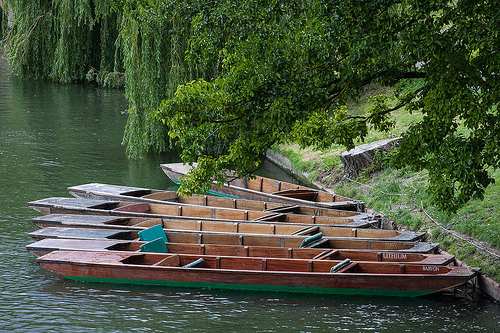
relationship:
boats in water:
[156, 152, 369, 213] [1, 66, 499, 332]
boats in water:
[64, 176, 385, 225] [1, 66, 499, 332]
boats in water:
[24, 190, 385, 232] [1, 66, 499, 332]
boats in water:
[28, 208, 426, 243] [1, 66, 499, 332]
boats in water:
[21, 222, 440, 255] [1, 66, 499, 332]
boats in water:
[20, 233, 460, 268] [1, 66, 499, 332]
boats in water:
[28, 248, 484, 298] [1, 66, 499, 332]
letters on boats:
[418, 263, 443, 275] [28, 248, 484, 298]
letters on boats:
[380, 249, 412, 261] [20, 233, 460, 268]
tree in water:
[116, 2, 232, 162] [1, 66, 499, 332]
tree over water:
[116, 2, 232, 162] [1, 66, 499, 332]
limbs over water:
[299, 80, 425, 140] [1, 66, 499, 332]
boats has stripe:
[28, 248, 484, 298] [61, 272, 438, 300]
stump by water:
[333, 133, 411, 175] [1, 66, 499, 332]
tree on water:
[116, 2, 232, 162] [1, 66, 499, 332]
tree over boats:
[116, 2, 232, 162] [156, 152, 369, 213]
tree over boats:
[116, 2, 232, 162] [64, 176, 385, 225]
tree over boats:
[116, 2, 232, 162] [24, 190, 385, 232]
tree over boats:
[116, 2, 232, 162] [28, 208, 426, 243]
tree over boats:
[116, 2, 232, 162] [21, 222, 440, 255]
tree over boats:
[116, 2, 232, 162] [20, 233, 460, 268]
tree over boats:
[116, 2, 232, 162] [28, 248, 484, 298]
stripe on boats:
[61, 272, 438, 300] [28, 248, 484, 298]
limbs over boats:
[299, 80, 425, 140] [28, 248, 484, 298]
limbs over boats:
[299, 80, 425, 140] [20, 233, 460, 268]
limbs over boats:
[299, 80, 425, 140] [156, 152, 369, 213]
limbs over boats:
[299, 80, 425, 140] [64, 176, 385, 225]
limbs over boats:
[299, 80, 425, 140] [24, 190, 385, 232]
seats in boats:
[141, 236, 174, 256] [20, 233, 460, 268]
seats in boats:
[135, 220, 173, 246] [21, 222, 440, 255]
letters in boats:
[418, 263, 443, 275] [28, 248, 484, 298]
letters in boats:
[380, 249, 412, 261] [20, 233, 460, 268]